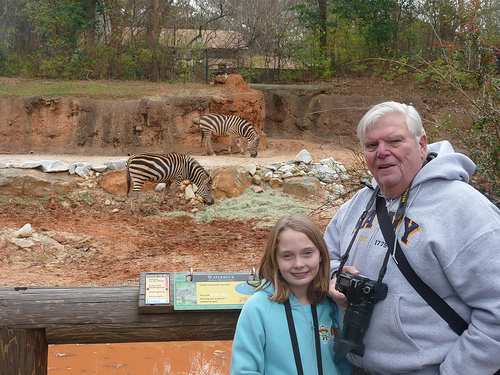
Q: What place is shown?
A: It is a zoo.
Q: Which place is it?
A: It is a zoo.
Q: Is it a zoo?
A: Yes, it is a zoo.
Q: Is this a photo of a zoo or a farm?
A: It is showing a zoo.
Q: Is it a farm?
A: No, it is a zoo.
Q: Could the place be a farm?
A: No, it is a zoo.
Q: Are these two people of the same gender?
A: No, they are both male and female.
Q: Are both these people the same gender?
A: No, they are both male and female.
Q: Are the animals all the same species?
A: Yes, all the animals are zebras.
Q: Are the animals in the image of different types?
A: No, all the animals are zebras.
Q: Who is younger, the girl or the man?
A: The girl is younger than the man.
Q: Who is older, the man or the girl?
A: The man is older than the girl.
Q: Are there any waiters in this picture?
A: No, there are no waiters.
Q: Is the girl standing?
A: Yes, the girl is standing.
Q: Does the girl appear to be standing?
A: Yes, the girl is standing.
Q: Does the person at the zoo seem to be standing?
A: Yes, the girl is standing.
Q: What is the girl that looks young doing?
A: The girl is standing.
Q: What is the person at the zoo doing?
A: The girl is standing.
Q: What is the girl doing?
A: The girl is standing.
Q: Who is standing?
A: The girl is standing.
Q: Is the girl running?
A: No, the girl is standing.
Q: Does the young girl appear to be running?
A: No, the girl is standing.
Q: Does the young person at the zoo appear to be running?
A: No, the girl is standing.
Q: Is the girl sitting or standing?
A: The girl is standing.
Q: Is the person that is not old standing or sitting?
A: The girl is standing.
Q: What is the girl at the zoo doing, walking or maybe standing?
A: The girl is standing.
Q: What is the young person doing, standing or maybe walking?
A: The girl is standing.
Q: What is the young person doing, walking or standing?
A: The girl is standing.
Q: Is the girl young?
A: Yes, the girl is young.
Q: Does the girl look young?
A: Yes, the girl is young.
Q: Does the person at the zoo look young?
A: Yes, the girl is young.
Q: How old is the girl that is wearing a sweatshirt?
A: The girl is young.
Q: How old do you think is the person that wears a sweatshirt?
A: The girl is young.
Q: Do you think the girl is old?
A: No, the girl is young.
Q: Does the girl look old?
A: No, the girl is young.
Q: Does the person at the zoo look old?
A: No, the girl is young.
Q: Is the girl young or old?
A: The girl is young.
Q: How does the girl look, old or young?
A: The girl is young.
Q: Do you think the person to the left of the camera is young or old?
A: The girl is young.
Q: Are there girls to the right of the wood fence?
A: Yes, there is a girl to the right of the fence.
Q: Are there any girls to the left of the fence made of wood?
A: No, the girl is to the right of the fence.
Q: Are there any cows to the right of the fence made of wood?
A: No, there is a girl to the right of the fence.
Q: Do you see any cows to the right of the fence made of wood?
A: No, there is a girl to the right of the fence.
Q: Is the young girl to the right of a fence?
A: Yes, the girl is to the right of a fence.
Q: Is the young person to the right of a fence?
A: Yes, the girl is to the right of a fence.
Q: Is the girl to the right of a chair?
A: No, the girl is to the right of a fence.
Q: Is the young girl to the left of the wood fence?
A: No, the girl is to the right of the fence.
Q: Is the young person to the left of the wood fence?
A: No, the girl is to the right of the fence.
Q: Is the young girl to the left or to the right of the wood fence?
A: The girl is to the right of the fence.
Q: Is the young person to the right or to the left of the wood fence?
A: The girl is to the right of the fence.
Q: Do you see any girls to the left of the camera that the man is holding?
A: Yes, there is a girl to the left of the camera.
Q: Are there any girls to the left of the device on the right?
A: Yes, there is a girl to the left of the camera.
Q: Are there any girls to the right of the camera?
A: No, the girl is to the left of the camera.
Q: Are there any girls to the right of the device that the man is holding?
A: No, the girl is to the left of the camera.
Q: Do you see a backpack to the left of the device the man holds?
A: No, there is a girl to the left of the camera.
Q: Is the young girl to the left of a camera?
A: Yes, the girl is to the left of a camera.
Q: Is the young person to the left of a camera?
A: Yes, the girl is to the left of a camera.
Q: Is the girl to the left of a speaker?
A: No, the girl is to the left of a camera.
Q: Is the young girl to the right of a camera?
A: No, the girl is to the left of a camera.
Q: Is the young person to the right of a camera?
A: No, the girl is to the left of a camera.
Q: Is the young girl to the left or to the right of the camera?
A: The girl is to the left of the camera.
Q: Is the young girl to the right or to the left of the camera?
A: The girl is to the left of the camera.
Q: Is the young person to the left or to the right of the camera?
A: The girl is to the left of the camera.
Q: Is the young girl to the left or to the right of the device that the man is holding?
A: The girl is to the left of the camera.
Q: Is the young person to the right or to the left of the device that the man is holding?
A: The girl is to the left of the camera.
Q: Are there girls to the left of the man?
A: Yes, there is a girl to the left of the man.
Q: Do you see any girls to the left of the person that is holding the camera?
A: Yes, there is a girl to the left of the man.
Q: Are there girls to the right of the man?
A: No, the girl is to the left of the man.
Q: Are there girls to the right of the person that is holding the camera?
A: No, the girl is to the left of the man.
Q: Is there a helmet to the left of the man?
A: No, there is a girl to the left of the man.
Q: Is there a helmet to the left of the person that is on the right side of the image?
A: No, there is a girl to the left of the man.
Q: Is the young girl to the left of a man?
A: Yes, the girl is to the left of a man.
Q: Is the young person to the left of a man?
A: Yes, the girl is to the left of a man.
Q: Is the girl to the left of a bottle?
A: No, the girl is to the left of a man.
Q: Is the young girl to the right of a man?
A: No, the girl is to the left of a man.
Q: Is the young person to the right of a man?
A: No, the girl is to the left of a man.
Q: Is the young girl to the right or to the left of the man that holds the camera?
A: The girl is to the left of the man.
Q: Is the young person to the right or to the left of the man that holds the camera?
A: The girl is to the left of the man.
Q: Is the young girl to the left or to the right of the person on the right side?
A: The girl is to the left of the man.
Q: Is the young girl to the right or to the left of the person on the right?
A: The girl is to the left of the man.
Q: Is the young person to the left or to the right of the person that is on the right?
A: The girl is to the left of the man.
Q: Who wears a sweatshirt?
A: The girl wears a sweatshirt.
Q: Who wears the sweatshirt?
A: The girl wears a sweatshirt.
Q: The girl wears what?
A: The girl wears a sweatshirt.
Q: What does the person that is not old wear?
A: The girl wears a sweatshirt.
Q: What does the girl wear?
A: The girl wears a sweatshirt.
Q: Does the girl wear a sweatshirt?
A: Yes, the girl wears a sweatshirt.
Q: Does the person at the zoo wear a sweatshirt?
A: Yes, the girl wears a sweatshirt.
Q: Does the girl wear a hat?
A: No, the girl wears a sweatshirt.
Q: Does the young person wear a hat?
A: No, the girl wears a sweatshirt.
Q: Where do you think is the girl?
A: The girl is at the zoo.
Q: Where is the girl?
A: The girl is at the zoo.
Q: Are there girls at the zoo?
A: Yes, there is a girl at the zoo.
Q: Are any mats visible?
A: No, there are no mats.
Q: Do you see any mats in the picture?
A: No, there are no mats.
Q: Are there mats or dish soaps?
A: No, there are no mats or dish soaps.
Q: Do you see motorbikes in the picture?
A: No, there are no motorbikes.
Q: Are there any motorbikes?
A: No, there are no motorbikes.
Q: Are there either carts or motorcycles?
A: No, there are no motorcycles or carts.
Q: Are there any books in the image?
A: No, there are no books.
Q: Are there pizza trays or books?
A: No, there are no books or pizza trays.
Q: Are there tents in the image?
A: No, there are no tents.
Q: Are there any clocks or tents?
A: No, there are no tents or clocks.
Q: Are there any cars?
A: No, there are no cars.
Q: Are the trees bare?
A: Yes, the trees are bare.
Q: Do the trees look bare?
A: Yes, the trees are bare.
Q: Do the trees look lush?
A: No, the trees are bare.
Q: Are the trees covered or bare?
A: The trees are bare.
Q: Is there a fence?
A: Yes, there is a fence.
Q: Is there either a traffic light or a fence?
A: Yes, there is a fence.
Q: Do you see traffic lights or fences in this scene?
A: Yes, there is a fence.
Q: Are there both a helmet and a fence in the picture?
A: No, there is a fence but no helmets.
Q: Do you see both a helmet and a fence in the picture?
A: No, there is a fence but no helmets.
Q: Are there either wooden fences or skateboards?
A: Yes, there is a wood fence.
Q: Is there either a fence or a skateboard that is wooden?
A: Yes, the fence is wooden.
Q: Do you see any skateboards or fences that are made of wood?
A: Yes, the fence is made of wood.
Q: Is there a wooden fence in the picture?
A: Yes, there is a wood fence.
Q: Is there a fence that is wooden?
A: Yes, there is a fence that is wooden.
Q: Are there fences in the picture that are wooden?
A: Yes, there is a fence that is wooden.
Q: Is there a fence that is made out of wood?
A: Yes, there is a fence that is made of wood.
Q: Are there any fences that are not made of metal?
A: Yes, there is a fence that is made of wood.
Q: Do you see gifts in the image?
A: No, there are no gifts.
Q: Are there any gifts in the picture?
A: No, there are no gifts.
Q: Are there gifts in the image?
A: No, there are no gifts.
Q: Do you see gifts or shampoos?
A: No, there are no gifts or shampoos.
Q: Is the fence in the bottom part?
A: Yes, the fence is in the bottom of the image.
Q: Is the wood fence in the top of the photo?
A: No, the fence is in the bottom of the image.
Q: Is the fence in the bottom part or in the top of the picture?
A: The fence is in the bottom of the image.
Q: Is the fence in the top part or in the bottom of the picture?
A: The fence is in the bottom of the image.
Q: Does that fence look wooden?
A: Yes, the fence is wooden.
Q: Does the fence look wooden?
A: Yes, the fence is wooden.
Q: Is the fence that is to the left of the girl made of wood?
A: Yes, the fence is made of wood.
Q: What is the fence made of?
A: The fence is made of wood.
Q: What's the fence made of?
A: The fence is made of wood.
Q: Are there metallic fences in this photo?
A: No, there is a fence but it is wooden.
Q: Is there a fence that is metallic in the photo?
A: No, there is a fence but it is wooden.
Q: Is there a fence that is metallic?
A: No, there is a fence but it is wooden.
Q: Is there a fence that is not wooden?
A: No, there is a fence but it is wooden.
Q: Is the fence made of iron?
A: No, the fence is made of wood.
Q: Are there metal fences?
A: No, there is a fence but it is made of wood.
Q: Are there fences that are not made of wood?
A: No, there is a fence but it is made of wood.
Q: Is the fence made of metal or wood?
A: The fence is made of wood.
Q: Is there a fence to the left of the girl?
A: Yes, there is a fence to the left of the girl.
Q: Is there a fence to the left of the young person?
A: Yes, there is a fence to the left of the girl.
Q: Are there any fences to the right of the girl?
A: No, the fence is to the left of the girl.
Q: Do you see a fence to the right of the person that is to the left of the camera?
A: No, the fence is to the left of the girl.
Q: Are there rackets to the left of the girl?
A: No, there is a fence to the left of the girl.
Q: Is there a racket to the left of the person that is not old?
A: No, there is a fence to the left of the girl.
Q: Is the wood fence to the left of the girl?
A: Yes, the fence is to the left of the girl.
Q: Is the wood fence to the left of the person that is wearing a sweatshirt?
A: Yes, the fence is to the left of the girl.